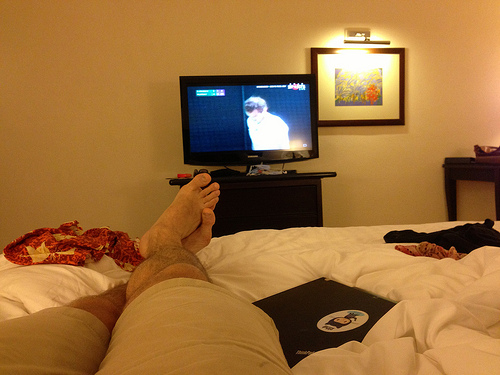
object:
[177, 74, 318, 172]
television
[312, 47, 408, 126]
painting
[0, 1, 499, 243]
wall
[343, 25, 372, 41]
light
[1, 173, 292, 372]
person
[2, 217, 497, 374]
bedf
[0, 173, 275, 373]
legs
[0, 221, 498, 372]
blanket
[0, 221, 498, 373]
bed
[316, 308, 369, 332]
sticker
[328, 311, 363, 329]
girl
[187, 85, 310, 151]
tennis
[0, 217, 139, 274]
clothing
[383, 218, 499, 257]
clothing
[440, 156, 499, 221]
table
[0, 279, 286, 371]
shorts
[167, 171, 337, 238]
stand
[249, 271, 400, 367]
laptop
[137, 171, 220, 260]
feet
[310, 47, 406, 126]
painting frame